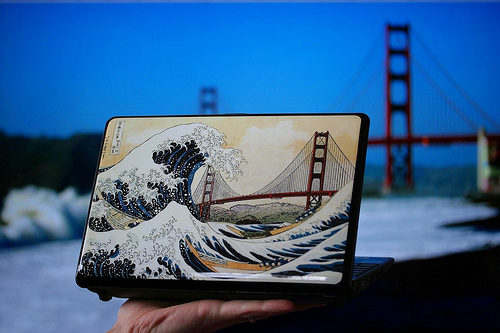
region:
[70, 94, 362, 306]
an image on a laptop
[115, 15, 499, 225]
this is a bridge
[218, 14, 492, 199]
the bridge is red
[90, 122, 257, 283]
ocean waves on image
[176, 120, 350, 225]
bridge on the image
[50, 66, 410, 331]
a hand holding a laptop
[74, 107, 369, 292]
a picture of a tsunami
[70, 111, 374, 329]
a hand holding a painting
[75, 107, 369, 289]
painting of a wave crashing into a bridge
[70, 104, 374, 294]
depiction of golden gate bridge beign flooded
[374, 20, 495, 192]
the golden gate bridge at night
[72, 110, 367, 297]
a small square shaped painting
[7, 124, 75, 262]
cliffside above water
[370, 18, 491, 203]
a bridge above the ocean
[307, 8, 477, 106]
night time on a bridge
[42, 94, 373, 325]
hand holding a picture by the sea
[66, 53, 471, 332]
a picture in a hand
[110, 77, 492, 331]
a picture of a bridge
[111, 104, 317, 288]
a picture of wave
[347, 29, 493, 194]
a birdge over water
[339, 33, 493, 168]
a large red brdige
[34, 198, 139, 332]
a body of water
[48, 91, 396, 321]
a computer that is open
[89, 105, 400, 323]
a laptop that is open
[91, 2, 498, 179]
a sky that is blue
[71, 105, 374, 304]
Japanese block print reproduction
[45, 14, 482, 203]
red gated bridge as seen in drawing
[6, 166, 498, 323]
ocean water under bridge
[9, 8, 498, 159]
deep blue sky without clouds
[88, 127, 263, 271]
large white foaming wave in picture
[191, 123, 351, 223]
red gated and wire bridge in picture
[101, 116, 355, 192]
yellow sky with white clouds in picture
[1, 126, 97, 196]
green hills in background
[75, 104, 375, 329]
person's hand holding artwork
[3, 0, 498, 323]
person comparing artwork to actual scene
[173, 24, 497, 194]
red suspension bridge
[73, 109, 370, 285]
laptop cover with picture of bridge and waves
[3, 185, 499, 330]
waves breaking on beach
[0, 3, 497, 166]
sky is deep blue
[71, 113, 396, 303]
laptop held in hand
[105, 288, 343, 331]
hand is holding laptop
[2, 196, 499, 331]
waves are white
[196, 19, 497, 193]
bridge is red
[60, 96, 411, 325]
a laptop over a hand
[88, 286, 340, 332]
hand under a laptop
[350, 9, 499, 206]
the bridge is red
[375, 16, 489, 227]
the bridge is above the water